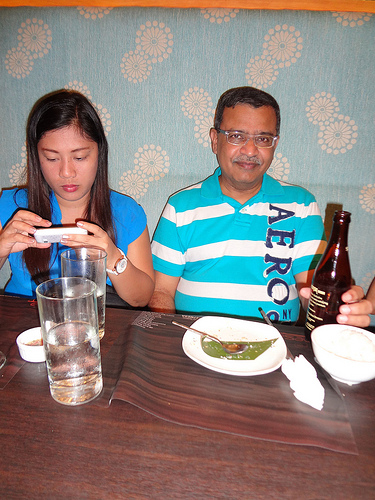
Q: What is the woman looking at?
A: Phone.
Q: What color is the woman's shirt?
A: Blue.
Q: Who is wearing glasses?
A: The man.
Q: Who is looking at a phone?
A: The woman.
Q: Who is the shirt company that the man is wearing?
A: Aeropostale.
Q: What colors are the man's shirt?
A: Blue and white.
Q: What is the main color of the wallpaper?
A: Light blue.